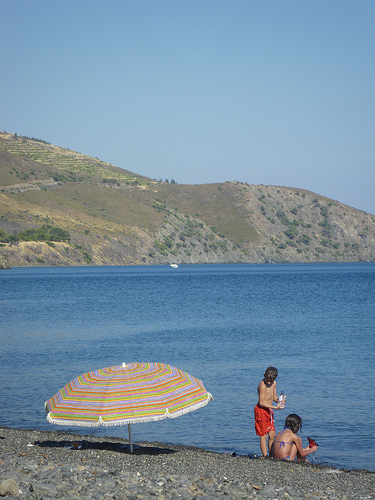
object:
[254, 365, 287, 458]
boy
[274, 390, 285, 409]
water bottle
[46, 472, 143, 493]
rocks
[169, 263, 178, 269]
boat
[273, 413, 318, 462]
girl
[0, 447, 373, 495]
ground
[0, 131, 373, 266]
hillside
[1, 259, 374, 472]
water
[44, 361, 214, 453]
umbrella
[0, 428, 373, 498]
beach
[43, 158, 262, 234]
ground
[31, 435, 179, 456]
shade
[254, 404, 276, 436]
shorts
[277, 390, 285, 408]
bottle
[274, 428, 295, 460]
bathing suit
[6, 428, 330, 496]
sand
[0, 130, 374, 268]
background